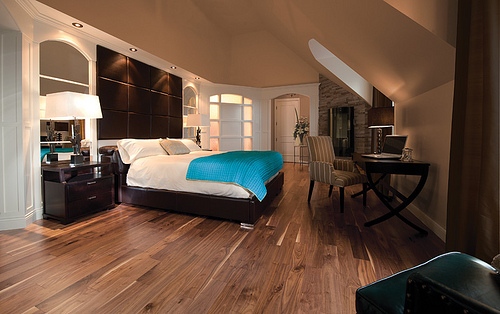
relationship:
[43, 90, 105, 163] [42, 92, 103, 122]
lamp with shade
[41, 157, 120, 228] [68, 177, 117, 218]
nightstand with drawers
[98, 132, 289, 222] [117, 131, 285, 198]
bed with linens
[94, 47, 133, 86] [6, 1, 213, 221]
rectangle on wall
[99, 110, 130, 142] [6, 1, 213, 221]
rectangle on wall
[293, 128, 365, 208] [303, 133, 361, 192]
chair with upholstery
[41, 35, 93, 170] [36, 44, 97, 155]
mirror in shape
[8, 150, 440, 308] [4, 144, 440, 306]
floor comprised of planks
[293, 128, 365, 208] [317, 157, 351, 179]
chair with cushion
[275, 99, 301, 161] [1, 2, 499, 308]
door from bedroom